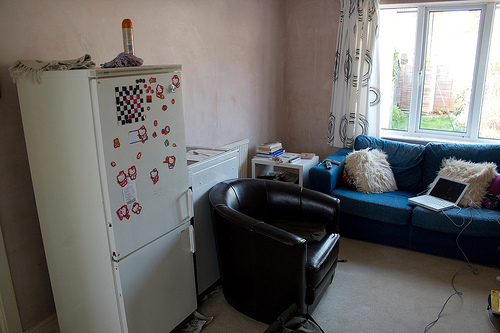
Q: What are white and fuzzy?
A: Pillows on the couch.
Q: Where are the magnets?
A: On the refrigerator.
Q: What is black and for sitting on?
A: The chair.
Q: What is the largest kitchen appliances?
A: Refrigerator.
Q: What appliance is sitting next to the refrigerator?
A: Stove.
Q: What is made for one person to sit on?
A: Chair.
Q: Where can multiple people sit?
A: Couch.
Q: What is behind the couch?
A: Window.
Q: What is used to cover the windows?
A: Curtains.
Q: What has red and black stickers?
A: Refrigerator door.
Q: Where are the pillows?
A: Couch.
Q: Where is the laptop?
A: On the couch.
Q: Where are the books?
A: Table.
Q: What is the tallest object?
A: This is a fridge.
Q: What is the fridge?
A: The fridge is white.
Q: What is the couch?
A: Blue.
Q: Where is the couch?
A: The couch is under the window.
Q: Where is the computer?
A: The computer is on the couch.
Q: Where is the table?
A: The table is next to the couch.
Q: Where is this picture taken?
A: In a home.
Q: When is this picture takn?
A: Daytime.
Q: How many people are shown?
A: None.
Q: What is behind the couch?
A: Windows.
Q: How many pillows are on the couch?
A: Two.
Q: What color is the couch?
A: Blue.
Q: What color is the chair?
A: Black.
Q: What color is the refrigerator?
A: White.